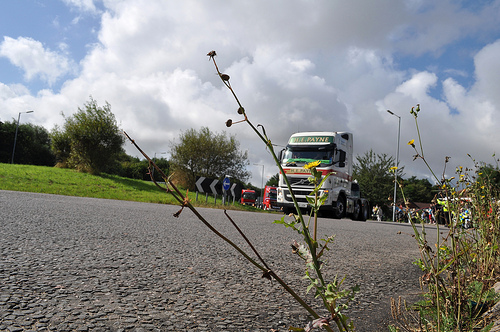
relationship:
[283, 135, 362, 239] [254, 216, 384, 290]
truck on road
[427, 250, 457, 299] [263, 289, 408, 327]
weeds on roadside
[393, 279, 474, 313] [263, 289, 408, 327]
flowers on roadside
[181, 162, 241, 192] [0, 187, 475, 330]
sign on side of road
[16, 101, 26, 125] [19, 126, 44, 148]
streetlight behind trees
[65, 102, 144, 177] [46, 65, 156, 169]
trees on hillside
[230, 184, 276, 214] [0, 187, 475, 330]
trucks on road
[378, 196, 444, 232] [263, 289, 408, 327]
people on roadside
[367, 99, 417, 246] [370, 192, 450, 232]
street lamp above people